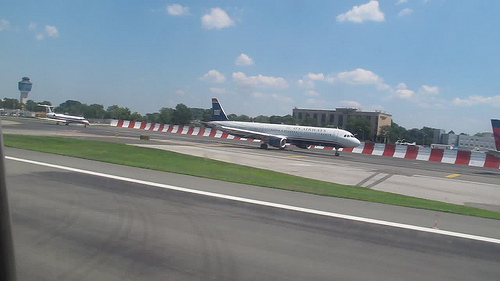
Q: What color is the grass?
A: Green.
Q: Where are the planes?
A: On the runway.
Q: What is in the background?
A: Trees.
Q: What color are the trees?
A: Green.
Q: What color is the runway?
A: Grey.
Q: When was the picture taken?
A: During the daytime.